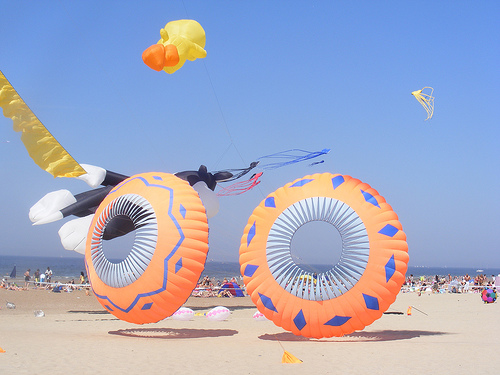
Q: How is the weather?
A: It is clear.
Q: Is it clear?
A: Yes, it is clear.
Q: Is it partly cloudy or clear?
A: It is clear.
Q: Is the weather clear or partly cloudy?
A: It is clear.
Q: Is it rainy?
A: No, it is clear.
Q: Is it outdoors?
A: Yes, it is outdoors.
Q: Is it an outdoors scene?
A: Yes, it is outdoors.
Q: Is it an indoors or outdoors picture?
A: It is outdoors.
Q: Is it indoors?
A: No, it is outdoors.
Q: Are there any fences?
A: No, there are no fences.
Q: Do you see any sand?
A: Yes, there is sand.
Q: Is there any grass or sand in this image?
A: Yes, there is sand.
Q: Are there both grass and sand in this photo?
A: No, there is sand but no grass.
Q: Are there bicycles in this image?
A: No, there are no bicycles.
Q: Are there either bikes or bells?
A: No, there are no bikes or bells.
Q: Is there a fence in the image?
A: No, there are no fences.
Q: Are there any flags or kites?
A: Yes, there is a kite.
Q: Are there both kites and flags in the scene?
A: No, there is a kite but no flags.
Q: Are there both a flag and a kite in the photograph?
A: No, there is a kite but no flags.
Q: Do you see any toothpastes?
A: No, there are no toothpastes.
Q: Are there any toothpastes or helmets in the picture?
A: No, there are no toothpastes or helmets.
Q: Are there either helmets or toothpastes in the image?
A: No, there are no toothpastes or helmets.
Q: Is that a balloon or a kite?
A: That is a kite.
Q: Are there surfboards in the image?
A: No, there are no surfboards.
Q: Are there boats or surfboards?
A: No, there are no surfboards or boats.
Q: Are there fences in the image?
A: No, there are no fences.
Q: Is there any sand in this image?
A: Yes, there is sand.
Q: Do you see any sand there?
A: Yes, there is sand.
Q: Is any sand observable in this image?
A: Yes, there is sand.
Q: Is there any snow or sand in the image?
A: Yes, there is sand.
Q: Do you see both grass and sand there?
A: No, there is sand but no grass.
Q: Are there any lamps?
A: No, there are no lamps.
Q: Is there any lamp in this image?
A: No, there are no lamps.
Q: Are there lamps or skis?
A: No, there are no lamps or skis.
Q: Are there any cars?
A: No, there are no cars.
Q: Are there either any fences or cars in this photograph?
A: No, there are no cars or fences.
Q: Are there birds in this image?
A: Yes, there is a bird.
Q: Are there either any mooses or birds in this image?
A: Yes, there is a bird.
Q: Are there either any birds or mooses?
A: Yes, there is a bird.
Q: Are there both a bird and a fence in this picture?
A: No, there is a bird but no fences.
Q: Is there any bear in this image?
A: No, there are no bears.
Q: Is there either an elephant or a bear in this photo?
A: No, there are no bears or elephants.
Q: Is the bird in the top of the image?
A: Yes, the bird is in the top of the image.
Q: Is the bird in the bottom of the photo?
A: No, the bird is in the top of the image.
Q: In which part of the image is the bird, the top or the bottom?
A: The bird is in the top of the image.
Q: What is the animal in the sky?
A: The animal is a bird.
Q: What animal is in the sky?
A: The animal is a bird.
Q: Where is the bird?
A: The bird is in the sky.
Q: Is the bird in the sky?
A: Yes, the bird is in the sky.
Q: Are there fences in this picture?
A: No, there are no fences.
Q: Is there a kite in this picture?
A: Yes, there is a kite.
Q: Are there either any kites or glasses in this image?
A: Yes, there is a kite.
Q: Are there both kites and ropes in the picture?
A: No, there is a kite but no ropes.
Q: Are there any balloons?
A: No, there are no balloons.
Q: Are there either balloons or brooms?
A: No, there are no balloons or brooms.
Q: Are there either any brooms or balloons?
A: No, there are no balloons or brooms.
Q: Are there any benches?
A: No, there are no benches.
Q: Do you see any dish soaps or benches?
A: No, there are no benches or dish soaps.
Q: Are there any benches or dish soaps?
A: No, there are no benches or dish soaps.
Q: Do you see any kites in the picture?
A: Yes, there is a kite.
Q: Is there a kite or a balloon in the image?
A: Yes, there is a kite.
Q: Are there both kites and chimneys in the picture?
A: No, there is a kite but no chimneys.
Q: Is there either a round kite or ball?
A: Yes, there is a round kite.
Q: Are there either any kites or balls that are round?
A: Yes, the kite is round.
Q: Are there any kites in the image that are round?
A: Yes, there is a round kite.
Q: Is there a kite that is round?
A: Yes, there is a kite that is round.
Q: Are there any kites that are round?
A: Yes, there is a kite that is round.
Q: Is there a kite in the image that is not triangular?
A: Yes, there is a round kite.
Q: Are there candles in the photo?
A: No, there are no candles.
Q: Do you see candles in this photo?
A: No, there are no candles.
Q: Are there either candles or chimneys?
A: No, there are no candles or chimneys.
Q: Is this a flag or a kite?
A: This is a kite.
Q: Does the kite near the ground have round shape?
A: Yes, the kite is round.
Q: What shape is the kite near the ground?
A: The kite is round.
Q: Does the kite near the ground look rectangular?
A: No, the kite is round.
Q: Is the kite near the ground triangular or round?
A: The kite is round.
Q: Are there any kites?
A: Yes, there is a kite.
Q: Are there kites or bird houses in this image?
A: Yes, there is a kite.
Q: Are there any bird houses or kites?
A: Yes, there is a kite.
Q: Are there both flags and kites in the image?
A: No, there is a kite but no flags.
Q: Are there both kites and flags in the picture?
A: No, there is a kite but no flags.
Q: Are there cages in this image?
A: No, there are no cages.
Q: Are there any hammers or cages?
A: No, there are no cages or hammers.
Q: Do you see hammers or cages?
A: No, there are no cages or hammers.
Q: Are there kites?
A: Yes, there is a kite.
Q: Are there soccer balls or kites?
A: Yes, there is a kite.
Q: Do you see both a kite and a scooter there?
A: No, there is a kite but no scooters.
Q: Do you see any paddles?
A: No, there are no paddles.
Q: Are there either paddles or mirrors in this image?
A: No, there are no paddles or mirrors.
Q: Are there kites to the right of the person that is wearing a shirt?
A: Yes, there is a kite to the right of the person.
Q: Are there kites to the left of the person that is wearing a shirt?
A: No, the kite is to the right of the person.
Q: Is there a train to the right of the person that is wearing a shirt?
A: No, there is a kite to the right of the person.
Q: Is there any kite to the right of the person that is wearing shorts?
A: Yes, there is a kite to the right of the person.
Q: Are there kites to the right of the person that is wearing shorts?
A: Yes, there is a kite to the right of the person.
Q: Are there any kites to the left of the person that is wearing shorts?
A: No, the kite is to the right of the person.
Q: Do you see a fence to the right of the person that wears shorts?
A: No, there is a kite to the right of the person.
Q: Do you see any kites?
A: Yes, there is a kite.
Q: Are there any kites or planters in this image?
A: Yes, there is a kite.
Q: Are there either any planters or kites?
A: Yes, there is a kite.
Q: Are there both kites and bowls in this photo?
A: No, there is a kite but no bowls.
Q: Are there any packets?
A: No, there are no packets.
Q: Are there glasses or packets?
A: No, there are no packets or glasses.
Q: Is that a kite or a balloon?
A: That is a kite.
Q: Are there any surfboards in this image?
A: No, there are no surfboards.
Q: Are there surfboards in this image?
A: No, there are no surfboards.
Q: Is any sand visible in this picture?
A: Yes, there is sand.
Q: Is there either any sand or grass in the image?
A: Yes, there is sand.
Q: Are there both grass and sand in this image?
A: No, there is sand but no grass.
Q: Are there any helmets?
A: No, there are no helmets.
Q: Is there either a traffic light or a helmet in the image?
A: No, there are no helmets or traffic lights.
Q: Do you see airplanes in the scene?
A: No, there are no airplanes.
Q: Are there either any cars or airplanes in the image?
A: No, there are no airplanes or cars.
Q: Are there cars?
A: No, there are no cars.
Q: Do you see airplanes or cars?
A: No, there are no cars or airplanes.